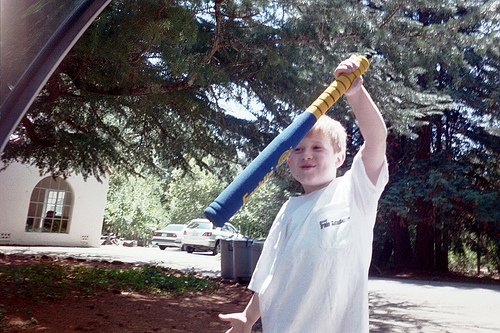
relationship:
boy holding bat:
[271, 85, 374, 330] [243, 162, 270, 191]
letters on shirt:
[316, 202, 341, 244] [320, 226, 380, 303]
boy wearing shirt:
[271, 85, 374, 330] [320, 226, 380, 303]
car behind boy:
[178, 218, 210, 251] [271, 85, 374, 330]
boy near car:
[271, 85, 374, 330] [178, 218, 210, 251]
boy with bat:
[271, 85, 374, 330] [243, 162, 270, 191]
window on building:
[30, 181, 72, 237] [15, 174, 96, 249]